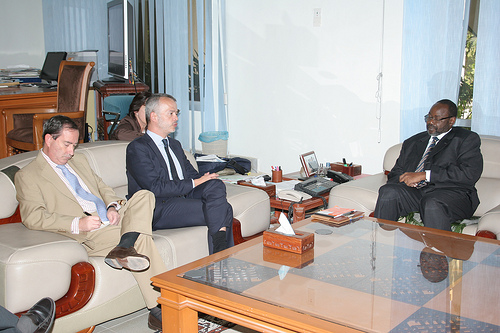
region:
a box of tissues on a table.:
[253, 201, 313, 269]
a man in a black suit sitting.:
[372, 98, 484, 248]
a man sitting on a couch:
[122, 93, 239, 253]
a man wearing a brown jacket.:
[11, 120, 174, 332]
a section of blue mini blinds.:
[180, 6, 210, 148]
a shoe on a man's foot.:
[100, 226, 153, 271]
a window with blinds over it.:
[111, 0, 221, 96]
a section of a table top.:
[349, 253, 434, 302]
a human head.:
[412, 93, 461, 139]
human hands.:
[385, 166, 432, 197]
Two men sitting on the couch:
[7, 95, 261, 315]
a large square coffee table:
[138, 200, 493, 332]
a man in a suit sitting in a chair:
[352, 80, 496, 266]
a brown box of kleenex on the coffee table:
[247, 195, 326, 262]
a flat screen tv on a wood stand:
[85, 3, 151, 130]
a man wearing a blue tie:
[20, 110, 122, 237]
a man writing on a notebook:
[21, 108, 140, 245]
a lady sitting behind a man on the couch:
[108, 83, 158, 140]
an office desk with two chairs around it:
[2, 48, 102, 148]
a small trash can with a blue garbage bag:
[192, 118, 235, 172]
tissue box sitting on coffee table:
[252, 208, 333, 278]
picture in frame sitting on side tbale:
[291, 136, 330, 185]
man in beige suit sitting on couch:
[5, 95, 155, 296]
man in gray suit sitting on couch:
[122, 85, 259, 243]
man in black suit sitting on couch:
[374, 81, 496, 266]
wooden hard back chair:
[17, 61, 112, 165]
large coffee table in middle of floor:
[138, 176, 495, 331]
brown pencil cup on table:
[264, 158, 289, 189]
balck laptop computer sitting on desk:
[26, 41, 67, 86]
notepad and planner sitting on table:
[307, 196, 373, 243]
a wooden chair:
[21, 60, 106, 125]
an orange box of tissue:
[261, 207, 320, 270]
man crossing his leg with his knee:
[41, 124, 158, 287]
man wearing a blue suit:
[146, 97, 234, 239]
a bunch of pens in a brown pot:
[268, 157, 288, 187]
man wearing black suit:
[378, 84, 486, 225]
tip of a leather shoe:
[14, 295, 66, 330]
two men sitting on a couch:
[5, 90, 276, 320]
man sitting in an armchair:
[356, 89, 497, 234]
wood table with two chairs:
[0, 51, 98, 141]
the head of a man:
[420, 93, 460, 137]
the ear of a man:
[444, 112, 458, 127]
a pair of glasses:
[421, 110, 457, 125]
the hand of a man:
[396, 167, 422, 191]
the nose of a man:
[66, 144, 76, 156]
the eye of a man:
[60, 138, 71, 150]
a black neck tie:
[159, 135, 181, 182]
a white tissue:
[273, 209, 297, 237]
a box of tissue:
[256, 221, 319, 255]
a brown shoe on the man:
[99, 245, 155, 275]